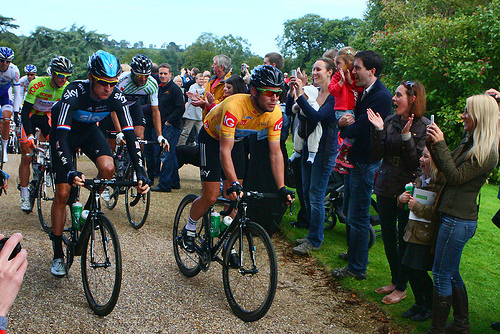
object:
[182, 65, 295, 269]
man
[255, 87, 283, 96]
sunglasses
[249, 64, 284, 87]
helmet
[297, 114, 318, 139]
sling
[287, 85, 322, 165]
infant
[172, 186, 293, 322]
bike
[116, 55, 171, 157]
man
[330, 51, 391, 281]
man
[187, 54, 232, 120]
man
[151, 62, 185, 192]
man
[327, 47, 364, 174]
child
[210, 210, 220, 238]
bottle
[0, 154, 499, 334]
ground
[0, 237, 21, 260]
camera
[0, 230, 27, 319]
hand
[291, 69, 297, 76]
camera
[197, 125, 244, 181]
shorts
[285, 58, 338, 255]
woman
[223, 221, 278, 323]
wheel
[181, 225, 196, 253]
foot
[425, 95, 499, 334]
woman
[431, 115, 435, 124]
cell phone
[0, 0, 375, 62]
sky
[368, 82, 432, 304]
woman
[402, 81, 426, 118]
hair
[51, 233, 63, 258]
sock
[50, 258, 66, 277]
foot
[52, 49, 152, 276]
man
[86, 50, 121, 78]
helmet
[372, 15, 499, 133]
trees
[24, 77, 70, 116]
top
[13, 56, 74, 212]
man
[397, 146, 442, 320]
child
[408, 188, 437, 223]
book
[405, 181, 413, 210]
bottle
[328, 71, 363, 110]
shirt